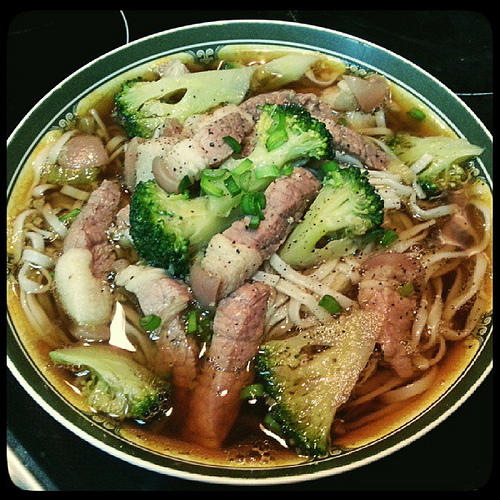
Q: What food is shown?
A: Broccoli and beef.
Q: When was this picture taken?
A: After cooking.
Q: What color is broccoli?
A: Green.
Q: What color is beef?
A: Brown.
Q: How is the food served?
A: In a bowl.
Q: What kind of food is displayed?
A: Chinese.